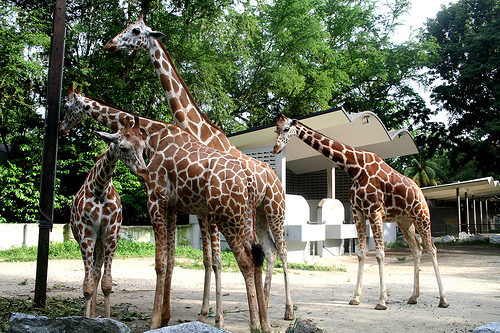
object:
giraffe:
[59, 80, 274, 332]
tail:
[246, 172, 265, 268]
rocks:
[6, 312, 130, 332]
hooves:
[374, 303, 387, 310]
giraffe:
[272, 113, 450, 310]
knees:
[376, 252, 386, 265]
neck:
[84, 96, 172, 159]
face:
[58, 100, 87, 136]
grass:
[0, 237, 348, 276]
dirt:
[0, 264, 26, 286]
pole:
[32, 0, 67, 309]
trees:
[0, 0, 108, 224]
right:
[303, 0, 500, 333]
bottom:
[0, 245, 499, 331]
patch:
[69, 197, 120, 225]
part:
[360, 115, 370, 126]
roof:
[224, 106, 419, 175]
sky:
[0, 0, 500, 171]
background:
[0, 0, 498, 222]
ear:
[149, 30, 167, 40]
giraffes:
[103, 10, 296, 327]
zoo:
[0, 107, 500, 333]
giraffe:
[68, 116, 150, 320]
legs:
[146, 193, 168, 331]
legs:
[214, 216, 264, 333]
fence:
[0, 224, 193, 257]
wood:
[5, 195, 20, 220]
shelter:
[188, 106, 420, 261]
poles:
[455, 188, 461, 234]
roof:
[420, 176, 500, 201]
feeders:
[315, 198, 357, 257]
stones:
[140, 320, 234, 333]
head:
[58, 82, 88, 137]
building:
[187, 101, 420, 264]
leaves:
[248, 0, 499, 90]